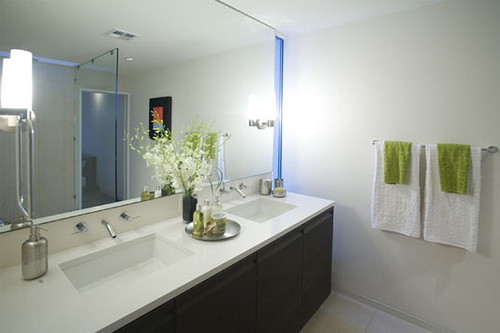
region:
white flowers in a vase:
[129, 112, 222, 218]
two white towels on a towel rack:
[370, 137, 497, 253]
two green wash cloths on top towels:
[377, 131, 499, 270]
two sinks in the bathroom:
[18, 161, 323, 296]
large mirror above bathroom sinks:
[6, 5, 318, 225]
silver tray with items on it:
[180, 198, 247, 243]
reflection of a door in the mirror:
[67, 70, 149, 211]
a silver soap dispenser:
[15, 210, 58, 282]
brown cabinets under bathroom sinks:
[102, 205, 369, 332]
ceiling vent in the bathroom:
[99, 20, 147, 48]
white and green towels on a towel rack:
[370, 136, 490, 251]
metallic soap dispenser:
[20, 222, 53, 279]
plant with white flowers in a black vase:
[129, 112, 228, 226]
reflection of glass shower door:
[6, 47, 120, 234]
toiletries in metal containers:
[255, 172, 291, 202]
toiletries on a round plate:
[186, 195, 245, 244]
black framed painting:
[138, 87, 174, 157]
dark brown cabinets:
[116, 202, 334, 330]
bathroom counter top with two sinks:
[0, 185, 337, 330]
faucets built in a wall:
[71, 205, 146, 242]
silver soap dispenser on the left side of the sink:
[16, 224, 56, 283]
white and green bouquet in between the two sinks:
[133, 126, 223, 223]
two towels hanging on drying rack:
[370, 136, 487, 252]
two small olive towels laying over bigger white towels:
[379, 136, 476, 196]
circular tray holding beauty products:
[180, 201, 245, 244]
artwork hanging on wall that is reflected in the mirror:
[139, 91, 178, 151]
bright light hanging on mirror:
[243, 86, 281, 133]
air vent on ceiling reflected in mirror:
[101, 25, 145, 47]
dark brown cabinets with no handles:
[92, 214, 371, 331]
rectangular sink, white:
[58, 230, 185, 293]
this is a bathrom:
[0, 1, 497, 326]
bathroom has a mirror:
[2, 4, 296, 231]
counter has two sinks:
[33, 191, 303, 286]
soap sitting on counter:
[22, 212, 50, 286]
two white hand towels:
[370, 136, 482, 267]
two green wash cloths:
[379, 139, 476, 199]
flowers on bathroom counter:
[118, 127, 222, 224]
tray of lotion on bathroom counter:
[182, 206, 244, 246]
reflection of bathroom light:
[0, 42, 35, 128]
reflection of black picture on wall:
[144, 92, 176, 147]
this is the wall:
[403, 57, 474, 101]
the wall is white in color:
[351, 59, 430, 112]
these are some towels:
[375, 149, 472, 234]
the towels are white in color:
[403, 198, 441, 228]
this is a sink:
[93, 244, 158, 285]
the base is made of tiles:
[13, 284, 50, 317]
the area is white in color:
[9, 288, 47, 328]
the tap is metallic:
[103, 222, 120, 242]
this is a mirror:
[28, 52, 133, 168]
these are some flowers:
[146, 117, 221, 191]